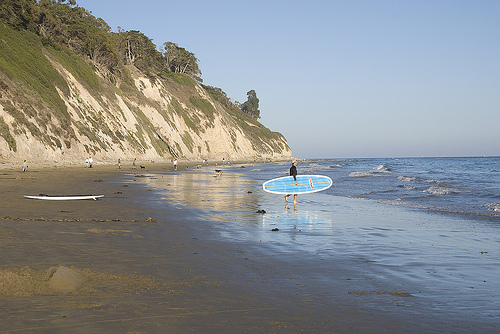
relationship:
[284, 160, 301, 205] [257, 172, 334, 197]
man carrying surfboard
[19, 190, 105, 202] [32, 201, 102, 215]
surfboard laying on sand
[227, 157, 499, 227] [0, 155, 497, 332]
ocean on sand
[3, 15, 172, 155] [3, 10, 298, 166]
grass of cliff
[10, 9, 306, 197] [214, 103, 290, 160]
grass on slope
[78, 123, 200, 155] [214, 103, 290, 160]
rocks on slope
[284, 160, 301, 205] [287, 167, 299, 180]
man with wetsuit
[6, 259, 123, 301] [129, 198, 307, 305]
sand on beach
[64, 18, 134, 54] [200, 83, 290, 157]
tree at top of slope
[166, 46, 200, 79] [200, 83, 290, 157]
tree at top of slope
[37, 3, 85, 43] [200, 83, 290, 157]
tree at top of slope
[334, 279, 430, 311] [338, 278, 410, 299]
seaweed on beach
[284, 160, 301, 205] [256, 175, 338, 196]
man holding surfboard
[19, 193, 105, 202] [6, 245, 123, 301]
surfboard lying on sand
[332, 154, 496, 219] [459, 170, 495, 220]
waves on water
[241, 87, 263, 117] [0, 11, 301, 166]
tree along top of hill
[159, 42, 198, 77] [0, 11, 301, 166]
tree along top of hill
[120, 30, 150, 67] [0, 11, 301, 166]
tree along top of hill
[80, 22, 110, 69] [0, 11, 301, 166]
tree along top of hill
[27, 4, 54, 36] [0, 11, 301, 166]
tree along top of hill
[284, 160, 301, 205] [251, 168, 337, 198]
man carrying surfboard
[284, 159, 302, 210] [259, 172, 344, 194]
blonde carrying surfboard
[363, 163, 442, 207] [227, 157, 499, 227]
waves in ocean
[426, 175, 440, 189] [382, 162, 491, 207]
person in water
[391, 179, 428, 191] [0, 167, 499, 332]
wave coming toward beach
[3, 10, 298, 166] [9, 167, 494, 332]
cliff above beach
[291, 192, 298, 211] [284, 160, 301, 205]
leg of man